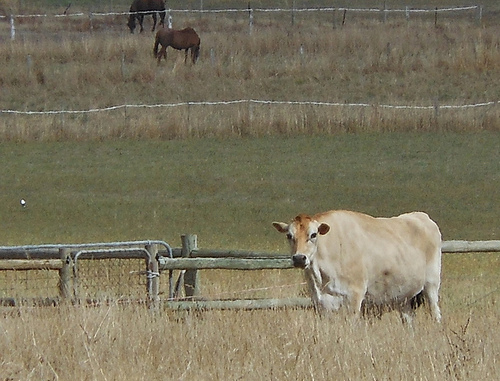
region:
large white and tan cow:
[282, 206, 441, 322]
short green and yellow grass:
[42, 164, 87, 196]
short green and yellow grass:
[124, 126, 174, 183]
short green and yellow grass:
[221, 159, 274, 195]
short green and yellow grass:
[343, 162, 380, 182]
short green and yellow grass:
[438, 146, 478, 187]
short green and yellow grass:
[59, 208, 101, 228]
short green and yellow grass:
[171, 142, 226, 196]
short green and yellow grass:
[73, 155, 145, 201]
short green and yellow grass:
[220, 126, 269, 181]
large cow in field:
[273, 195, 455, 318]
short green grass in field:
[47, 149, 100, 185]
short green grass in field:
[28, 147, 129, 196]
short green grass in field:
[90, 176, 128, 198]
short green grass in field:
[212, 152, 265, 182]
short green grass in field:
[152, 160, 226, 207]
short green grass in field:
[298, 134, 329, 156]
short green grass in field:
[401, 127, 467, 158]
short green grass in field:
[422, 142, 498, 175]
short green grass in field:
[285, 149, 358, 180]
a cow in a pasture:
[218, 153, 495, 363]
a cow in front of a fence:
[184, 165, 491, 337]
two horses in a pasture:
[93, 0, 219, 70]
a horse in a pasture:
[150, 25, 200, 61]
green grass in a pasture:
[4, 123, 499, 191]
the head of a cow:
[266, 210, 332, 270]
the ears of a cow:
[263, 220, 330, 236]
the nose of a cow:
[288, 246, 312, 269]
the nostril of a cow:
[299, 253, 307, 262]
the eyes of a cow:
[281, 228, 317, 241]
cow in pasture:
[3, 115, 493, 380]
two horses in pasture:
[102, 0, 260, 85]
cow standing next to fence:
[260, 202, 460, 342]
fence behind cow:
[192, 205, 473, 328]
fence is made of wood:
[171, 237, 315, 329]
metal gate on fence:
[68, 235, 180, 344]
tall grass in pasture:
[183, 309, 383, 375]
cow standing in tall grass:
[270, 208, 464, 349]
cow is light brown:
[265, 200, 475, 344]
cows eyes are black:
[280, 230, 327, 243]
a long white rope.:
[2, 94, 499, 119]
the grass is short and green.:
[112, 164, 260, 199]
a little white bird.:
[13, 195, 33, 209]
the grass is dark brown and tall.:
[304, 33, 439, 78]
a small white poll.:
[245, 5, 259, 33]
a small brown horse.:
[145, 22, 210, 64]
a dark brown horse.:
[116, 3, 169, 35]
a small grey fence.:
[66, 239, 155, 326]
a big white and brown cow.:
[270, 202, 447, 327]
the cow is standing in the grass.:
[266, 206, 455, 344]